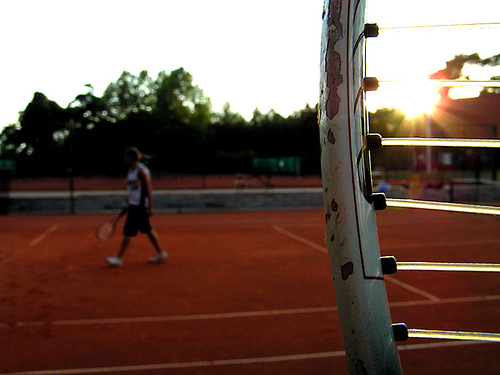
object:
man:
[105, 146, 170, 266]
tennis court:
[0, 202, 500, 375]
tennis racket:
[95, 205, 129, 242]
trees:
[0, 89, 76, 180]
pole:
[316, 0, 405, 375]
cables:
[377, 79, 500, 88]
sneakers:
[147, 250, 169, 263]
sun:
[395, 81, 442, 118]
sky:
[0, 0, 500, 153]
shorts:
[122, 204, 153, 236]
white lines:
[0, 304, 337, 327]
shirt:
[126, 162, 153, 208]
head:
[123, 147, 141, 165]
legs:
[104, 204, 142, 267]